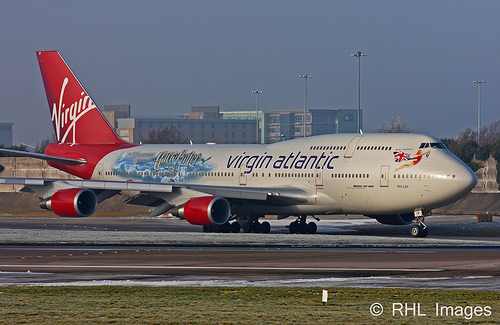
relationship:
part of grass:
[98, 290, 137, 321] [132, 286, 330, 324]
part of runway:
[37, 218, 150, 283] [44, 203, 328, 276]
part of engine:
[50, 181, 102, 215] [61, 175, 103, 224]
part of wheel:
[235, 222, 244, 237] [229, 218, 244, 235]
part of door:
[241, 162, 250, 185] [234, 157, 253, 189]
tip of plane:
[458, 161, 483, 198] [37, 58, 477, 241]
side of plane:
[155, 151, 426, 207] [37, 58, 477, 241]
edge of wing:
[13, 148, 86, 162] [7, 139, 109, 173]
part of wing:
[10, 141, 53, 163] [7, 139, 109, 173]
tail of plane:
[32, 36, 126, 153] [37, 58, 477, 241]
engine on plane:
[61, 175, 103, 224] [37, 58, 477, 241]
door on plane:
[234, 157, 253, 189] [37, 58, 477, 241]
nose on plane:
[452, 156, 480, 203] [37, 58, 477, 241]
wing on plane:
[7, 139, 109, 173] [37, 58, 477, 241]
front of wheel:
[415, 225, 423, 240] [411, 222, 421, 237]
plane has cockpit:
[37, 58, 477, 241] [390, 135, 479, 212]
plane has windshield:
[37, 58, 477, 241] [418, 124, 470, 158]